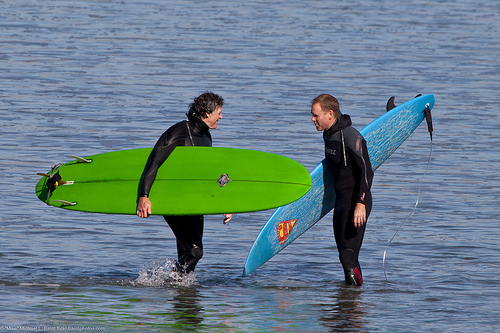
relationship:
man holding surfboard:
[80, 69, 330, 296] [33, 144, 313, 229]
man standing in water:
[310, 92, 373, 288] [0, 1, 498, 331]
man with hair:
[134, 90, 233, 280] [182, 93, 229, 120]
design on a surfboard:
[275, 217, 297, 243] [241, 92, 435, 277]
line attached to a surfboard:
[381, 134, 433, 282] [241, 92, 435, 277]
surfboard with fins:
[237, 84, 442, 296] [412, 107, 442, 136]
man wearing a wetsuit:
[310, 92, 373, 288] [321, 120, 393, 283]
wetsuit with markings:
[321, 120, 393, 283] [352, 130, 367, 159]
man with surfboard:
[310, 92, 373, 288] [241, 92, 435, 277]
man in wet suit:
[134, 90, 233, 280] [136, 120, 242, 300]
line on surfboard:
[381, 102, 433, 282] [237, 84, 442, 296]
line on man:
[381, 102, 433, 282] [310, 92, 373, 288]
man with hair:
[305, 92, 347, 130] [317, 94, 335, 108]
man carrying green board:
[134, 90, 233, 280] [31, 142, 314, 219]